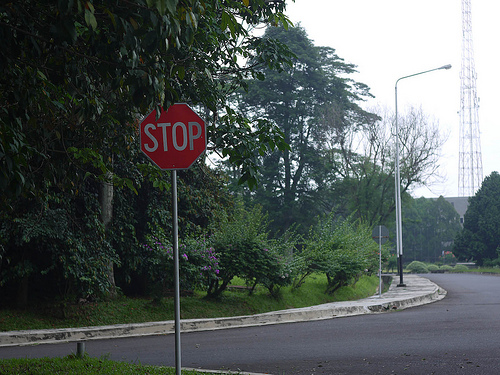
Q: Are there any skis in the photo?
A: No, there are no skis.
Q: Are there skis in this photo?
A: No, there are no skis.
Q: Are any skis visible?
A: No, there are no skis.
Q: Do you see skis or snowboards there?
A: No, there are no skis or snowboards.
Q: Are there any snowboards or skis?
A: No, there are no skis or snowboards.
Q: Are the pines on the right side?
A: No, the pines are on the left of the image.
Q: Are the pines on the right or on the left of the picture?
A: The pines are on the left of the image.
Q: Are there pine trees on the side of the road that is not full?
A: Yes, there are pine trees on the side of the road.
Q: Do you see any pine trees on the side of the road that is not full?
A: Yes, there are pine trees on the side of the road.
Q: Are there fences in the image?
A: No, there are no fences.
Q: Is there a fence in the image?
A: No, there are no fences.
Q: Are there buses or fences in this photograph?
A: No, there are no fences or buses.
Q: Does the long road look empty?
A: Yes, the road is empty.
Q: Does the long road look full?
A: No, the road is empty.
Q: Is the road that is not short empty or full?
A: The road is empty.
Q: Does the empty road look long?
A: Yes, the road is long.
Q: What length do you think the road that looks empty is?
A: The road is long.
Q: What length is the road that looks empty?
A: The road is long.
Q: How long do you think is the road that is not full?
A: The road is long.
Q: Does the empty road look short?
A: No, the road is long.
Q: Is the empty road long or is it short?
A: The road is long.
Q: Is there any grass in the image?
A: Yes, there is grass.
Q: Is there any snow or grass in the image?
A: Yes, there is grass.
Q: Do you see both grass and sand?
A: No, there is grass but no sand.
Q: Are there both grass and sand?
A: No, there is grass but no sand.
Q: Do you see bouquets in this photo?
A: No, there are no bouquets.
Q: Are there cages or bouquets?
A: No, there are no bouquets or cages.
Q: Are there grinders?
A: No, there are no grinders.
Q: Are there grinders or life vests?
A: No, there are no grinders or life vests.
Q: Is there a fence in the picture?
A: No, there are no fences.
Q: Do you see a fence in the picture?
A: No, there are no fences.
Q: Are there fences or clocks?
A: No, there are no fences or clocks.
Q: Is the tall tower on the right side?
A: Yes, the tower is on the right of the image.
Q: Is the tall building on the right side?
A: Yes, the tower is on the right of the image.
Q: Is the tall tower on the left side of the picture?
A: No, the tower is on the right of the image.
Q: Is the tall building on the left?
A: No, the tower is on the right of the image.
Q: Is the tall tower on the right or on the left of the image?
A: The tower is on the right of the image.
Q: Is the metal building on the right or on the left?
A: The tower is on the right of the image.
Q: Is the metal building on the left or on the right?
A: The tower is on the right of the image.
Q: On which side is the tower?
A: The tower is on the right of the image.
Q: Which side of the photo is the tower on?
A: The tower is on the right of the image.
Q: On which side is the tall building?
A: The tower is on the right of the image.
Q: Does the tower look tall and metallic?
A: Yes, the tower is tall and metallic.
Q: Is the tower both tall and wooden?
A: No, the tower is tall but metallic.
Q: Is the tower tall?
A: Yes, the tower is tall.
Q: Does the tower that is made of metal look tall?
A: Yes, the tower is tall.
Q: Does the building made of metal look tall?
A: Yes, the tower is tall.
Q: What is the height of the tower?
A: The tower is tall.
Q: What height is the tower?
A: The tower is tall.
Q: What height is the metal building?
A: The tower is tall.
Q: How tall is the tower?
A: The tower is tall.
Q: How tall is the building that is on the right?
A: The tower is tall.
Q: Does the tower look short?
A: No, the tower is tall.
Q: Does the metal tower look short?
A: No, the tower is tall.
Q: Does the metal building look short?
A: No, the tower is tall.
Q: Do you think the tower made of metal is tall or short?
A: The tower is tall.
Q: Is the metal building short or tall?
A: The tower is tall.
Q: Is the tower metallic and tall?
A: Yes, the tower is metallic and tall.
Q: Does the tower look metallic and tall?
A: Yes, the tower is metallic and tall.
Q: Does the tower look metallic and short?
A: No, the tower is metallic but tall.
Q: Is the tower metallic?
A: Yes, the tower is metallic.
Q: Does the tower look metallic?
A: Yes, the tower is metallic.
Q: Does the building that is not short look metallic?
A: Yes, the tower is metallic.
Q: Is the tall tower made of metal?
A: Yes, the tower is made of metal.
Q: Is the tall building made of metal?
A: Yes, the tower is made of metal.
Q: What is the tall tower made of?
A: The tower is made of metal.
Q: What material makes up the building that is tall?
A: The tower is made of metal.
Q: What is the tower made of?
A: The tower is made of metal.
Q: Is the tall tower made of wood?
A: No, the tower is made of metal.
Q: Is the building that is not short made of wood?
A: No, the tower is made of metal.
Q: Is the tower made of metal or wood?
A: The tower is made of metal.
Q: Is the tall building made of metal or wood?
A: The tower is made of metal.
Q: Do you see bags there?
A: No, there are no bags.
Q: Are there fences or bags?
A: No, there are no bags or fences.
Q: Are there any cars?
A: No, there are no cars.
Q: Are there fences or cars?
A: No, there are no cars or fences.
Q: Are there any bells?
A: No, there are no bells.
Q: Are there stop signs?
A: Yes, there is a stop sign.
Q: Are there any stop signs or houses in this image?
A: Yes, there is a stop sign.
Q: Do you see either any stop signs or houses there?
A: Yes, there is a stop sign.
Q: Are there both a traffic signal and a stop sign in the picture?
A: No, there is a stop sign but no traffic lights.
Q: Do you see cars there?
A: No, there are no cars.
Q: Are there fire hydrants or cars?
A: No, there are no cars or fire hydrants.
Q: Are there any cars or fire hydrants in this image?
A: No, there are no cars or fire hydrants.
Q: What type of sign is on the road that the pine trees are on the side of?
A: The sign is a stop sign.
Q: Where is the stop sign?
A: The stop sign is on the road.